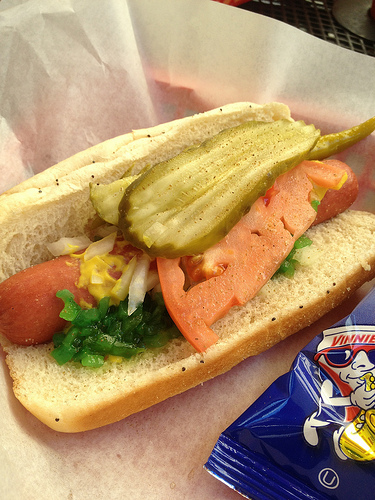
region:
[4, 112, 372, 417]
this is a hotdog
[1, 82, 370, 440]
a hotdog with a variety of toppings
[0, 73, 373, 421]
this is a Chicago dog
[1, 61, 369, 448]
a Chicago-style hot dog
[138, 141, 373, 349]
this is a slice of tomato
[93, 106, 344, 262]
this is a crinkled-slice pickle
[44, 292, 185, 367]
this is green relish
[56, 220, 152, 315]
this is mustard and chopped onion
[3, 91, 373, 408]
there are poppy seeds on the bun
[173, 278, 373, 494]
this is a bag of potato chips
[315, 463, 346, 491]
a U printed on bag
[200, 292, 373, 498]
blue bag of snacks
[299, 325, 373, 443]
character on the bag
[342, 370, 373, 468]
saxaphone in his hand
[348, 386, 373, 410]
the character's right hand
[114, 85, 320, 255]
green pickle on bun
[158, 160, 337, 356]
tomato on the bun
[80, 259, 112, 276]
mustard on hot dog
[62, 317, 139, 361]
relish on the hot dog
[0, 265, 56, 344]
end of the hotdog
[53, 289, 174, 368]
Relish on the bread.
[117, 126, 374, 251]
Pickle on top of the sandwich.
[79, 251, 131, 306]
The mustard on the sandwich.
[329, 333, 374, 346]
The word VINNIE on the chip bag.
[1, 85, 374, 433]
Hotdog with toppings on a sandwich.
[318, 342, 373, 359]
Red sunglasses on the chip bag.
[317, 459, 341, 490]
U in a circle on the chip bag.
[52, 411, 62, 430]
Speck of pepper on the bread.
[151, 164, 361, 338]
The tomato on the sandwich.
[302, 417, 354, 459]
Two white feet on the chip bag.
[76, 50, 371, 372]
a hot dog on a paper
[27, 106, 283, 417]
a hotdog on a bun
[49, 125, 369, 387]
a cooked hotodg on a bun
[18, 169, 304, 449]
a hotdog with tomoto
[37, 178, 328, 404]
a hotdog with relish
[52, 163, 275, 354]
hotdog with onions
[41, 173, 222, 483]
hotdog with yellow mustard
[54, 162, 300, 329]
a hotdog with pickle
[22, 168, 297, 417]
a pickle on a hotdog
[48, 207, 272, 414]
relish on a hotdog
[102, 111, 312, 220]
pickle on a bun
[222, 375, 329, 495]
chips in a bag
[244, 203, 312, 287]
tomatoe on a bun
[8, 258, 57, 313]
hot dog on a bun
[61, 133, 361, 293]
hot dog on a bun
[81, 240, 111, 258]
onion on a hot dog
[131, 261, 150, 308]
onion on a hot dog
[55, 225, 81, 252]
onion on a hot dog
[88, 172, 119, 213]
pickle on a hot dog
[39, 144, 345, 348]
hot dog on plate